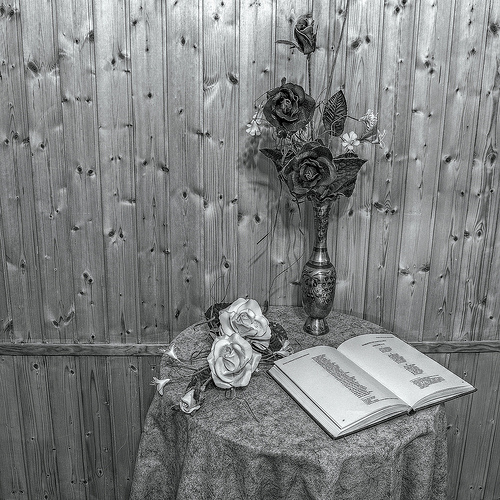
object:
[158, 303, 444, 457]
table top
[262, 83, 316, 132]
flower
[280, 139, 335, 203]
flower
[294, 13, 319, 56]
flower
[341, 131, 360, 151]
flower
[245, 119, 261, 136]
flower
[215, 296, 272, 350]
flowers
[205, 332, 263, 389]
flower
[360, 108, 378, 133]
flower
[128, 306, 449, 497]
table cloth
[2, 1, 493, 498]
photograph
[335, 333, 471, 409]
pages.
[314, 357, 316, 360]
words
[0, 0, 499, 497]
panel wall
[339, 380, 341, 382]
letters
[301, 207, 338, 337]
vase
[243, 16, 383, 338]
display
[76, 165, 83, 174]
holes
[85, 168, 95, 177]
holes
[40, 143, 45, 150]
holes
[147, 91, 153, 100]
holes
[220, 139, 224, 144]
holes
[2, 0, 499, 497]
wall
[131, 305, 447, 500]
table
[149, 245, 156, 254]
knot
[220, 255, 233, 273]
knot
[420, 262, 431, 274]
knot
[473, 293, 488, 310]
knot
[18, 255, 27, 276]
knot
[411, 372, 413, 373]
letters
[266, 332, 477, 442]
book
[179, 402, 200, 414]
petal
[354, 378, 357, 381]
words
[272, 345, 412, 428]
page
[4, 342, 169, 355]
line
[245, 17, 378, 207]
bouquet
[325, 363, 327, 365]
words